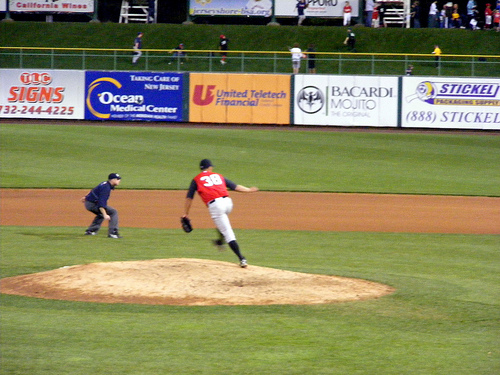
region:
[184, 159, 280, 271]
player's shirt is red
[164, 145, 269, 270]
player's pants is white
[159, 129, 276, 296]
player is wearing long black socks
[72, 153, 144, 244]
man is wearing blue baseball cap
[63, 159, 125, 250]
man is wearing blue shirt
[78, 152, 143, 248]
man's pants are gray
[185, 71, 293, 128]
yellow sign on fence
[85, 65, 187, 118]
blue sign on fence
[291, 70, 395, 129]
white sign on fence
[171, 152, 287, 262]
player holding baseball glove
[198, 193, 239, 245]
baseball player in white unifrom pants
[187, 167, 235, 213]
baseball player in orange jersey with white number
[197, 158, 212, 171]
blue baseball hat on baseball player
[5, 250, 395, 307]
dirt mound in middle of green grass baseball field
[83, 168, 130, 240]
umpire crouching and watching field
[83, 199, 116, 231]
umpire wearing gray pants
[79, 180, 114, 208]
umpire wearing blue shirt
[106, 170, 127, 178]
umpire wearing blue baseball cap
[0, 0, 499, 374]
A baseball game is being played.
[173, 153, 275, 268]
The pitcher is running.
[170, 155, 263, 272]
The pitcher is watching his teammates.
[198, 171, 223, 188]
The pitcher's player number is 38.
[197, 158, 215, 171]
The pitcher is wearing a black cap.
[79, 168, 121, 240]
The player is standing near the base.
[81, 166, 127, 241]
The player is trying to steal a base.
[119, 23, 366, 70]
Some people are playing outside the fence.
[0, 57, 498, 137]
Some signs are posted along the fence.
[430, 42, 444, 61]
The man is wearing a yellow jacket.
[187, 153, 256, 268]
this is a baseball player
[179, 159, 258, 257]
the player is running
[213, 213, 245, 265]
these are the legs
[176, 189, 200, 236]
this is the hand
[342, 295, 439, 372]
this is the pitch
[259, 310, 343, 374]
the pitch is green in color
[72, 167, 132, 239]
the player is squatting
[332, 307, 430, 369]
the grass is short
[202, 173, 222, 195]
the jersey is red in color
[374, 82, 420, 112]
this is the poster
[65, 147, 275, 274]
Two men in the foreground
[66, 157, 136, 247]
A side view of a baseball player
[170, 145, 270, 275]
Baseball player is wearing a red jersey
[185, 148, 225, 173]
Baseball player is wearing a cap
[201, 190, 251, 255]
Baseball player is wearing white pants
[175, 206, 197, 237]
Baseball player is holding a catcher glove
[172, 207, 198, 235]
Catcher glove is black in color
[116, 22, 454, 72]
People in the background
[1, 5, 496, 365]
Photo was taken outdoors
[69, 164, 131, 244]
Baseball player is wearing a blue shirt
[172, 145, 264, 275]
pitcher on brown mound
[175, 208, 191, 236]
black leather pitcher mitt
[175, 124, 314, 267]
pitcher on the mound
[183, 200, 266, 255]
white pants on the player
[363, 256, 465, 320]
green grass on ground